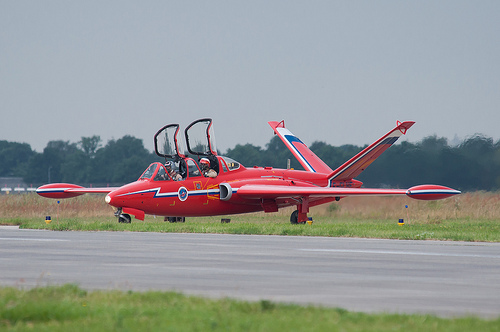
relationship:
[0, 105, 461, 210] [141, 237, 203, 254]
plane on airstrip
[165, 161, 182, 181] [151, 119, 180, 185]
man in cockpit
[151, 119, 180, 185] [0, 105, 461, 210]
cockpit in plane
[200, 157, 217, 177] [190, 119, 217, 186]
man in cockpit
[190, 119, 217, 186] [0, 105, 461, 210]
cockpit in plane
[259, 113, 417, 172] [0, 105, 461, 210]
tail of plane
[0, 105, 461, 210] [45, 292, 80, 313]
plane in grass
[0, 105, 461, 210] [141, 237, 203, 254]
plane near airstrip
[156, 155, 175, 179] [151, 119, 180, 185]
man in cockpit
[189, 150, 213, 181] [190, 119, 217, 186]
man in cockpit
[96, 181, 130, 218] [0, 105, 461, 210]
nose of plane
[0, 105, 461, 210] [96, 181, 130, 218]
plane has nose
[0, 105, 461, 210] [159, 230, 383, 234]
plane on ground